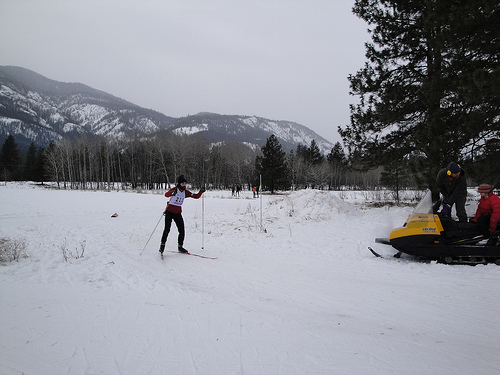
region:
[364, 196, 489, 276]
Yellow and black snowmobile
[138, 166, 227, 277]
Person cross country skiing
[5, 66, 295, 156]
Snow covered mountains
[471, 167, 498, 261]
Person wearing red sitting on a snowmobile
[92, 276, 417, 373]
Patch of snow with ski prints in it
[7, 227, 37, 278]
Dead plants sticking out of the snow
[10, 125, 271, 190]
Row of trees in front of the mountains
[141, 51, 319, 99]
Grey cloudless sky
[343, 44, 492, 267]
Large pine tree behind snowmobiles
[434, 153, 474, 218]
Man wearing all black with yellow earmuffs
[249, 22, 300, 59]
part of a cloud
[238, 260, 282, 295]
part of a cloud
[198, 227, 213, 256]
part of a hooker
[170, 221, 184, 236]
part of a trouser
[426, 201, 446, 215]
part of a glass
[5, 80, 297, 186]
snow is on mountains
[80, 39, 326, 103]
the sky is gray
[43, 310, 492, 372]
the snow is white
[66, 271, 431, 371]
snow is on ground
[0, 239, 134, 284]
the branches are brown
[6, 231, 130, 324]
branches in the snow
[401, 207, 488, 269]
snow mobiles are yellow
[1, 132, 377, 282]
trees behind the skier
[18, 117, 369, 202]
the trees are dark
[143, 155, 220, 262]
woman holding ski poles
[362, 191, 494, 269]
yellow snowmobile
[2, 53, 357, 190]
mountain landscape after snow has fallen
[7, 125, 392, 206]
trees without leaves on them in winter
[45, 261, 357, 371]
snow with tracks on them from skis, snowmobiles, etc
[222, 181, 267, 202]
group of people on the mountainside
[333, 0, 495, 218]
a large evergreen tree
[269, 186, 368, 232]
a pile of shoveled snow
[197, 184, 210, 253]
ski pole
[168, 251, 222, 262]
a red ski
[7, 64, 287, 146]
a range of mountains touching an overcast sky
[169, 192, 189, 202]
the number 311 on a person's chest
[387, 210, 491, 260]
a yellow snowmobile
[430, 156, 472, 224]
a man wearing yellow ear muffs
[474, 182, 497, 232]
a blonde woman wearing a red coat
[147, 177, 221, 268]
a woman on skis holding two poles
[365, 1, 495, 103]
an evergreen tree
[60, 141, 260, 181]
a group of trees without leaves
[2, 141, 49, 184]
a group of evergreen trees in front of a mountain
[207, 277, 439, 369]
white snow on the ground